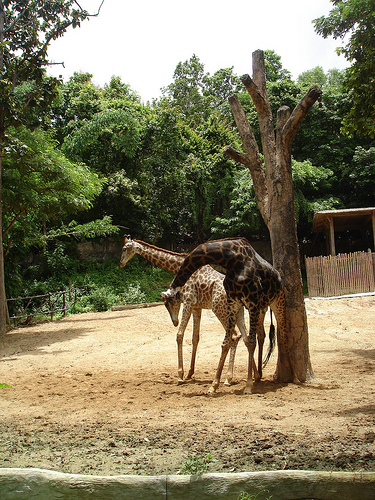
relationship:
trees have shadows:
[313, 0, 373, 147] [337, 339, 374, 431]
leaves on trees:
[340, 130, 346, 138] [313, 0, 373, 147]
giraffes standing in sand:
[159, 236, 303, 387] [4, 299, 375, 365]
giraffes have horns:
[159, 236, 303, 387] [161, 293, 167, 300]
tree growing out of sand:
[220, 49, 328, 389] [4, 299, 375, 365]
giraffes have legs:
[159, 236, 303, 387] [245, 301, 261, 392]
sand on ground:
[4, 299, 375, 365] [2, 295, 374, 472]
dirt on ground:
[5, 426, 371, 469] [2, 295, 374, 472]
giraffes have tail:
[159, 236, 303, 387] [264, 308, 277, 372]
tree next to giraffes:
[220, 49, 328, 389] [159, 236, 303, 387]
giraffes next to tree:
[159, 236, 303, 387] [220, 49, 328, 389]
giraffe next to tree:
[116, 236, 261, 387] [220, 49, 328, 389]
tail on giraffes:
[264, 308, 277, 372] [159, 236, 303, 387]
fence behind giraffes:
[305, 249, 374, 300] [159, 236, 303, 387]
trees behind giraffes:
[313, 0, 373, 147] [159, 236, 303, 387]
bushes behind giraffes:
[4, 252, 174, 321] [159, 236, 303, 387]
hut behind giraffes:
[310, 205, 374, 254] [159, 236, 303, 387]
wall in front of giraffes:
[1, 467, 374, 500] [159, 236, 303, 387]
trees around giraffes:
[313, 0, 373, 147] [159, 236, 303, 387]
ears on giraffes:
[163, 291, 173, 296] [159, 236, 303, 387]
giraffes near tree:
[159, 236, 303, 387] [220, 49, 328, 389]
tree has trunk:
[220, 49, 328, 389] [266, 220, 315, 384]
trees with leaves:
[313, 0, 373, 147] [340, 130, 346, 138]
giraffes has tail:
[159, 236, 303, 387] [264, 308, 277, 372]